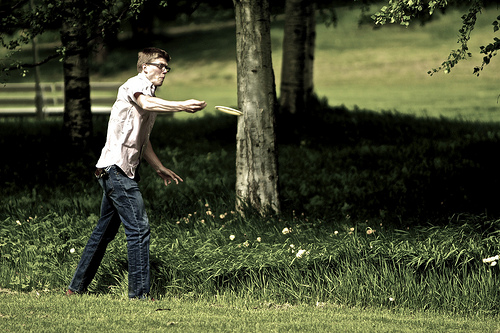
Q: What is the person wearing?
A: Pants.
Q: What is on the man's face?
A: Glasses.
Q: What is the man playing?
A: Frisbee.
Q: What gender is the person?
A: Male.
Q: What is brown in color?
A: Tree trunk.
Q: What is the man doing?
A: Throwing an object.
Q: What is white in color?
A: The shirt.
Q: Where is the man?
A: In the grass.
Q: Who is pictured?
A: A man.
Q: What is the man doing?
A: Throwing a frisbee.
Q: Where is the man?
A: In a field.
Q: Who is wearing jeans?
A: The man.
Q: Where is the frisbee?
A: In the air.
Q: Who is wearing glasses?
A: The man.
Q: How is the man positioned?
A: Standing.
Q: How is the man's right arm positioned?
A: Outstretched.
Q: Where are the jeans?
A: On the man.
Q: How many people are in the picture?
A: One.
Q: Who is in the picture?
A: A man.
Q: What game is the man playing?
A: Frisbee.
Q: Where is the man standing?
A: In the grass.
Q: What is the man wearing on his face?
A: Glasses.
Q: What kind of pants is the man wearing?
A: Jeans.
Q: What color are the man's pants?
A: Blue.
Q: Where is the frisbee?
A: The air.